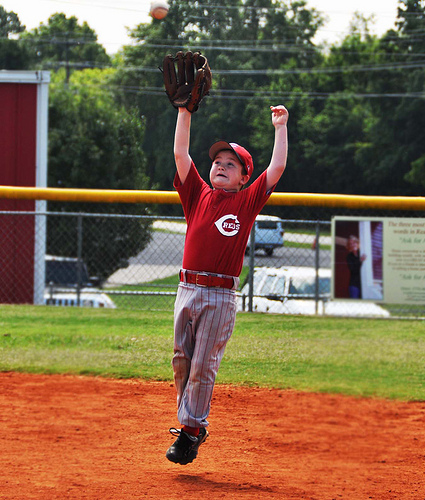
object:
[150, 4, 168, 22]
baseball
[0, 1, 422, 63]
mid-air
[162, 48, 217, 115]
mitt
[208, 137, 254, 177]
cap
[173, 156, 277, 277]
uniform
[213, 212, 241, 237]
chicago reds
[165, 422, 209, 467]
cleats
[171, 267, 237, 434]
pants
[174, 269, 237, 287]
belt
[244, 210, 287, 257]
jeep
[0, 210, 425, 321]
fence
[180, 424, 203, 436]
socks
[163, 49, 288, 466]
boy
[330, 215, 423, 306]
sign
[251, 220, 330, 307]
chain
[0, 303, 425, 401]
grass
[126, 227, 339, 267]
road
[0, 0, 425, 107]
electric wires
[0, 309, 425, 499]
baseball court